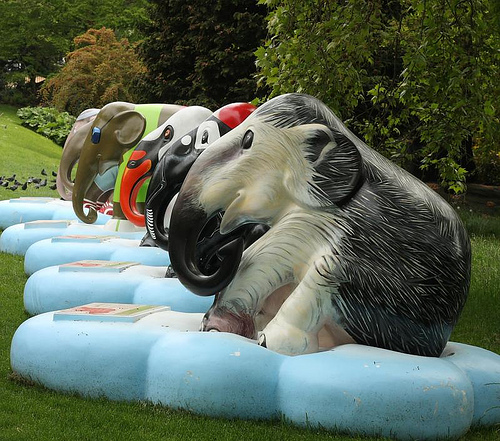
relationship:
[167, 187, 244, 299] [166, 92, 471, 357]
trunk of elephant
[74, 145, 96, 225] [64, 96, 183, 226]
green trunk of statue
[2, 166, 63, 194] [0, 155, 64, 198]
birds on grass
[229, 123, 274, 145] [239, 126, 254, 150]
eye has eye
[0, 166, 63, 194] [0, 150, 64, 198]
birds on grass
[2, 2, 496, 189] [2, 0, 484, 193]
trees in background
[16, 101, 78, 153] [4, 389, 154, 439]
bushes on ground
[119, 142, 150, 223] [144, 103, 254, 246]
trunk on statute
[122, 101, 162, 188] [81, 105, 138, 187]
torso on elephant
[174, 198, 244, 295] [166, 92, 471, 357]
trunk on elephant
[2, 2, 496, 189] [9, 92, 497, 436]
trees lined behind statue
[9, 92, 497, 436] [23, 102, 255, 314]
statue lined behind statue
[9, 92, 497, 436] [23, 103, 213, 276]
statue lined behind statue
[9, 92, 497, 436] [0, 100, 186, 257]
statue lined behind statue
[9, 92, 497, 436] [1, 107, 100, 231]
statue lined behind statue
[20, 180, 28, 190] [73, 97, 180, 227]
bird behind statue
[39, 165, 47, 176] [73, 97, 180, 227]
bird behind statue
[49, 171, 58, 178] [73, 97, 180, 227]
bird behind statue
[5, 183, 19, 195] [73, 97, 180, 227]
bird behind statue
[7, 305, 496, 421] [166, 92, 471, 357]
base under elephant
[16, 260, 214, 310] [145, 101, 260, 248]
base under statue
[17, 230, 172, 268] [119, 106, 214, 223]
base under statue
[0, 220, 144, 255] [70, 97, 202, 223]
base under statue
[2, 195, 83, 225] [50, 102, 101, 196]
base under statue